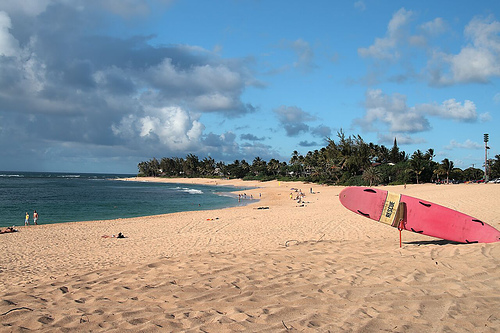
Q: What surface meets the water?
A: Sand.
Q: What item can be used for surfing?
A: Surfboard.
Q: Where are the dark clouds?
A: Above the water.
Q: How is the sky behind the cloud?
A: Blue.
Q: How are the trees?
A: Green.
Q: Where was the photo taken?
A: The beach.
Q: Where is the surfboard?
A: The sand.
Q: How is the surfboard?
A: Pink and yellow.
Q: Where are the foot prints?
A: The sand.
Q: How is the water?
A: Blue.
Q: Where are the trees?
A: Background.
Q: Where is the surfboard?
A: The beach.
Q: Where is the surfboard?
A: The beach.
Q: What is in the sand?
A: A surfboard on the sand.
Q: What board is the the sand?
A: A red surfboard on the sand.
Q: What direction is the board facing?
A: A red surfboard on its side.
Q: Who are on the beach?
A: People on the beach.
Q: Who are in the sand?
A: People on the sand.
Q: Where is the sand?
A: On the ground.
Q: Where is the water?
A: In front of the sand.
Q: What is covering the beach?
A: Sand.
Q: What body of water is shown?
A: An ocean.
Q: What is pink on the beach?
A: A surfboard.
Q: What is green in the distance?
A: Trees.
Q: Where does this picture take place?
A: At a beach.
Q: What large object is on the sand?
A: A surf rescue board.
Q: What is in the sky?
A: Clouds.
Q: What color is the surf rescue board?
A: Red.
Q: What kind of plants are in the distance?
A: Trees.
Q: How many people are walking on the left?
A: Two.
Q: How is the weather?
A: Partly sunny.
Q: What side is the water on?
A: The left.